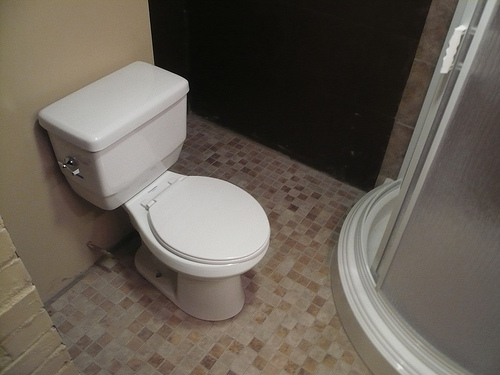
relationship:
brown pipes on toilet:
[78, 237, 125, 287] [27, 68, 297, 331]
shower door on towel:
[329, 2, 497, 374] [438, 24, 466, 75]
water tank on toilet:
[37, 60, 189, 210] [39, 61, 272, 322]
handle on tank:
[57, 156, 78, 181] [52, 57, 190, 211]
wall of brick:
[0, 219, 76, 374] [0, 228, 20, 262]